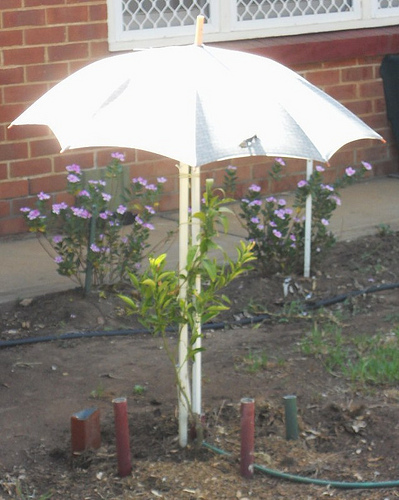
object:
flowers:
[66, 172, 82, 184]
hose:
[198, 438, 398, 489]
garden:
[163, 366, 334, 482]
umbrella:
[7, 14, 386, 455]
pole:
[111, 397, 134, 478]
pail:
[381, 52, 399, 169]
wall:
[10, 28, 69, 72]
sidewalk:
[4, 171, 397, 305]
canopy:
[6, 45, 386, 170]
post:
[239, 396, 256, 480]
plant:
[116, 178, 257, 450]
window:
[107, 1, 399, 52]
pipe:
[282, 396, 300, 441]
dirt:
[101, 353, 142, 379]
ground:
[38, 324, 132, 382]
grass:
[295, 315, 398, 381]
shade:
[50, 322, 158, 407]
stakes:
[303, 161, 313, 279]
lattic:
[121, 0, 209, 31]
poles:
[176, 161, 188, 450]